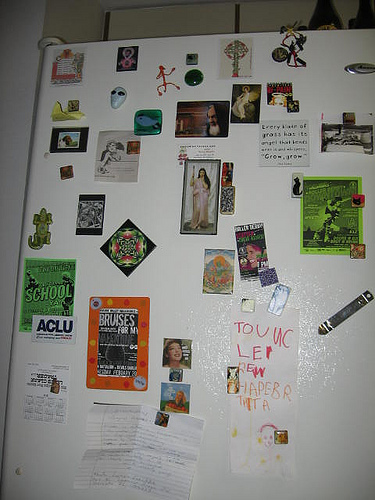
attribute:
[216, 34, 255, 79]
cross — celtic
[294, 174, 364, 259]
flyer — green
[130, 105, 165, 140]
magnet — green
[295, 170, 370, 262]
flyer — green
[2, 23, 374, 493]
refrigerator — white, blue, lined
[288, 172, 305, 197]
cat — black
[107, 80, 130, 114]
alien face — magnrt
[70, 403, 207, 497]
paper — written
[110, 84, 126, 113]
magnet — green, pink, white, there\, alien, orange, religous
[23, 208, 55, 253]
lizard — green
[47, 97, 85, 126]
paper — yellow, written\, green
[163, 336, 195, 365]
picture — small, drawn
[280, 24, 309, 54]
figure — orange, written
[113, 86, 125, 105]
alien — white